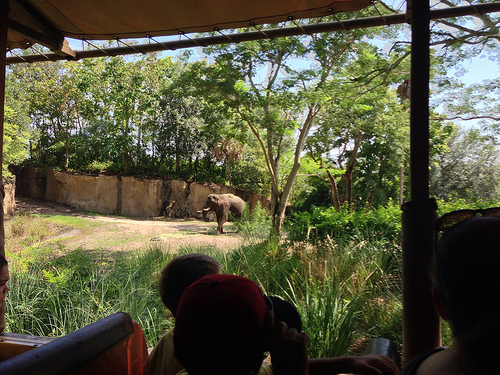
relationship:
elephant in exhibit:
[198, 196, 249, 231] [11, 28, 409, 333]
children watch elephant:
[154, 215, 500, 374] [198, 196, 249, 231]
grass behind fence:
[12, 243, 401, 327] [1, 334, 44, 360]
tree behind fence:
[177, 37, 414, 257] [1, 334, 44, 360]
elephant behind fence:
[198, 196, 249, 231] [1, 334, 44, 360]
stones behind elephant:
[19, 166, 240, 217] [198, 196, 249, 231]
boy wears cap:
[172, 274, 317, 373] [180, 275, 269, 338]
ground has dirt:
[13, 196, 357, 266] [15, 197, 249, 248]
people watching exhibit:
[154, 215, 500, 374] [11, 28, 409, 333]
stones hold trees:
[19, 166, 240, 217] [33, 70, 265, 177]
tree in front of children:
[177, 37, 414, 257] [154, 215, 500, 374]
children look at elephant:
[154, 215, 500, 374] [198, 196, 249, 231]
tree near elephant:
[177, 37, 414, 257] [198, 196, 249, 231]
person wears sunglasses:
[405, 208, 499, 375] [433, 207, 499, 268]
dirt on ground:
[15, 197, 249, 248] [13, 196, 357, 266]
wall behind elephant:
[19, 166, 240, 217] [198, 196, 249, 231]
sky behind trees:
[429, 20, 500, 200] [33, 70, 265, 177]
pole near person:
[400, 3, 441, 374] [405, 208, 499, 375]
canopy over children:
[6, 2, 498, 61] [154, 215, 500, 374]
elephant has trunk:
[198, 196, 249, 231] [200, 200, 210, 223]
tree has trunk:
[177, 37, 414, 257] [267, 184, 287, 244]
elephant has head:
[198, 196, 249, 231] [207, 195, 217, 213]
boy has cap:
[172, 274, 317, 373] [180, 275, 269, 338]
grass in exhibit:
[12, 243, 401, 327] [11, 28, 409, 333]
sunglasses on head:
[433, 207, 499, 268] [431, 212, 500, 323]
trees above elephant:
[33, 70, 265, 177] [198, 196, 249, 231]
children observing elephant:
[154, 215, 500, 374] [198, 196, 249, 231]